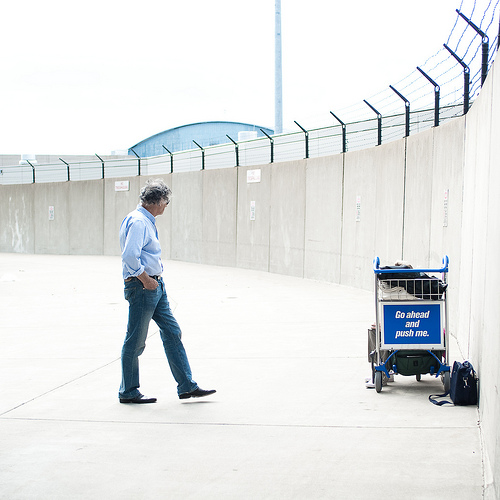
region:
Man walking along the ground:
[110, 167, 235, 427]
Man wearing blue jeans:
[99, 162, 220, 424]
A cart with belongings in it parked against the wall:
[357, 222, 484, 427]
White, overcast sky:
[39, 14, 258, 99]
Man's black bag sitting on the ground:
[417, 357, 487, 420]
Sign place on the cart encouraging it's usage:
[372, 298, 452, 356]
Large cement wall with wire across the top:
[208, 127, 389, 297]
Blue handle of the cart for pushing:
[364, 251, 459, 278]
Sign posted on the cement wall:
[104, 175, 135, 198]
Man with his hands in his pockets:
[111, 165, 226, 412]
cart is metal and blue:
[356, 246, 457, 411]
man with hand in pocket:
[105, 175, 222, 407]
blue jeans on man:
[114, 274, 203, 402]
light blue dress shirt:
[114, 208, 162, 290]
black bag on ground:
[430, 357, 480, 414]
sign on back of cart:
[375, 298, 445, 355]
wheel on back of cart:
[367, 360, 394, 397]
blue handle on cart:
[363, 248, 457, 283]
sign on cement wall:
[243, 162, 266, 189]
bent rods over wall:
[224, 128, 246, 175]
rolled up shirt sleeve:
[129, 256, 153, 284]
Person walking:
[46, 130, 203, 404]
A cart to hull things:
[361, 241, 461, 423]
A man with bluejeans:
[107, 286, 200, 401]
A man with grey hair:
[121, 181, 236, 261]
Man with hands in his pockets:
[114, 256, 201, 339]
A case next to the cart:
[381, 321, 488, 429]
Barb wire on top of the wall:
[89, 161, 153, 168]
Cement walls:
[194, 161, 321, 319]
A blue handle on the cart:
[370, 249, 485, 434]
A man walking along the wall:
[77, 173, 227, 423]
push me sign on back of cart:
[373, 294, 453, 364]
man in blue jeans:
[100, 172, 222, 409]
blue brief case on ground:
[425, 352, 480, 414]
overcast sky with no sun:
[48, 10, 254, 106]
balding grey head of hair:
[130, 168, 175, 221]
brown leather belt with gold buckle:
[116, 267, 166, 284]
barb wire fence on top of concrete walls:
[197, 82, 486, 175]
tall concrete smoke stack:
[262, 2, 303, 144]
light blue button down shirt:
[112, 198, 168, 290]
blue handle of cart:
[370, 257, 457, 281]